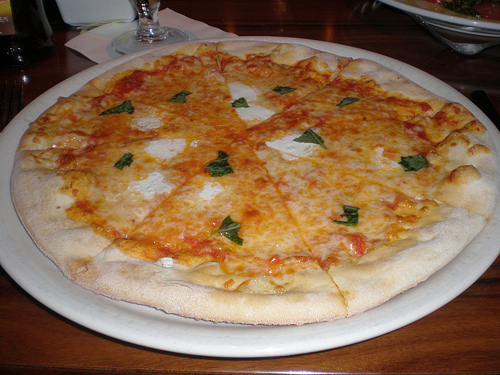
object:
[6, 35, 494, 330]
pizza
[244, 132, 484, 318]
slice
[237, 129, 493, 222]
basil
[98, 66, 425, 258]
cheese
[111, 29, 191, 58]
bottom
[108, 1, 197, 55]
glass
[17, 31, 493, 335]
crust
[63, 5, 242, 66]
napkin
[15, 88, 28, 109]
part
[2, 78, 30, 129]
fork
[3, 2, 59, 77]
bottle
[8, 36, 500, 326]
topping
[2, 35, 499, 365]
plate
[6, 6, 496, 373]
table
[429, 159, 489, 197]
bubbles